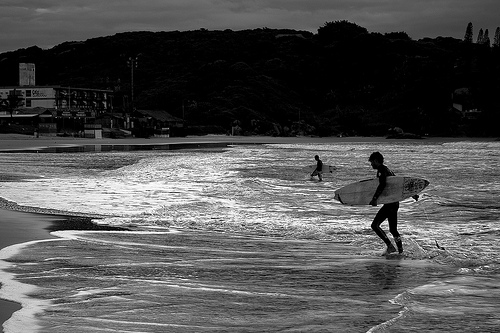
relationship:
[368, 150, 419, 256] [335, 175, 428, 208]
man carrying surfboard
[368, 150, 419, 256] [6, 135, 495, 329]
man in water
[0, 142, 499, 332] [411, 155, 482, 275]
ripples in water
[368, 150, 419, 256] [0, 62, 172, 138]
man at building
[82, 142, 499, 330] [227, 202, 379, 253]
water has waves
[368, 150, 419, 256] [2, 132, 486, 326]
man in beach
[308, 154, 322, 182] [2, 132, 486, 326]
people in beach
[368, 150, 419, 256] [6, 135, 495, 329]
man close water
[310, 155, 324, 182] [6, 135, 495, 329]
people close water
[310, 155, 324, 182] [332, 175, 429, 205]
people carry surfboard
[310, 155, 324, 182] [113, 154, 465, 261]
people in water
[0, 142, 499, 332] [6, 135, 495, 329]
ripples in water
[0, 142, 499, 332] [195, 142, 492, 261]
ripples in water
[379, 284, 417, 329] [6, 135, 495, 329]
ripples in water